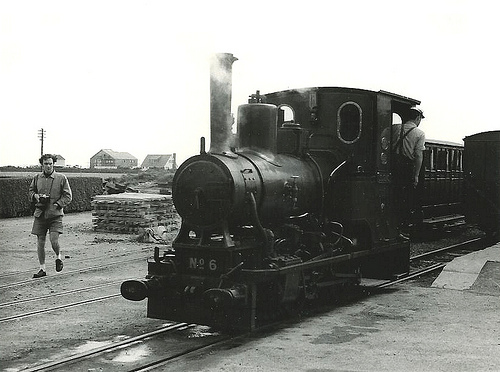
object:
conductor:
[393, 105, 425, 236]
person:
[388, 105, 424, 240]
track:
[55, 289, 173, 362]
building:
[50, 149, 180, 174]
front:
[116, 136, 261, 338]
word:
[186, 252, 221, 273]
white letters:
[178, 251, 221, 272]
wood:
[88, 189, 180, 240]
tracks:
[0, 238, 499, 370]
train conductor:
[393, 105, 425, 234]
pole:
[34, 126, 49, 162]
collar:
[402, 120, 414, 131]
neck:
[400, 118, 414, 128]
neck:
[38, 171, 59, 178]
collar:
[37, 171, 64, 178]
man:
[27, 151, 73, 281]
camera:
[34, 192, 50, 212]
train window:
[331, 99, 363, 144]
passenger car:
[407, 123, 474, 250]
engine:
[122, 85, 420, 331]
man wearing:
[29, 151, 72, 282]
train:
[120, 85, 499, 332]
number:
[189, 253, 225, 276]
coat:
[25, 171, 75, 220]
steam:
[199, 45, 247, 145]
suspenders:
[391, 123, 421, 155]